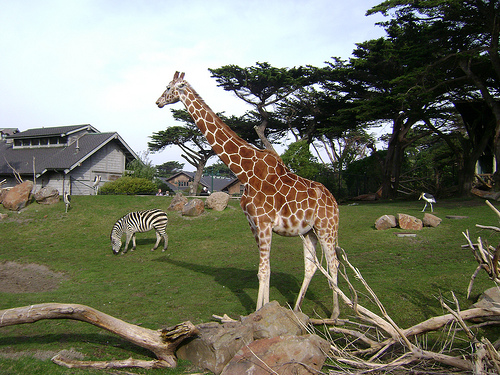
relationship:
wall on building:
[81, 125, 173, 216] [19, 102, 126, 224]